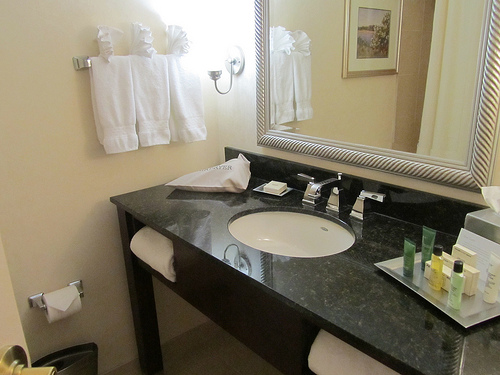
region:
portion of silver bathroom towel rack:
[70, 53, 97, 69]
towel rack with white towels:
[70, 18, 213, 148]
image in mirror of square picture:
[338, 1, 413, 86]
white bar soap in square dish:
[253, 174, 297, 204]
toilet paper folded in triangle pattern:
[45, 288, 86, 325]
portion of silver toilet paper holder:
[17, 289, 46, 311]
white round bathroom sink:
[229, 204, 364, 264]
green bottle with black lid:
[445, 260, 471, 308]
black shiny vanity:
[113, 148, 493, 373]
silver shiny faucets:
[296, 161, 383, 233]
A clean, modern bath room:
[13, 13, 486, 360]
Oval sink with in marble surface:
[221, 202, 363, 268]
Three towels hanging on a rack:
[83, 58, 210, 155]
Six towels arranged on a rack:
[68, 23, 204, 146]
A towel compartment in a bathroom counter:
[111, 203, 215, 305]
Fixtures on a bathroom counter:
[296, 166, 388, 229]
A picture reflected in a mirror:
[336, 3, 465, 190]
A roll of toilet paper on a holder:
[20, 277, 97, 326]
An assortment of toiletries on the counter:
[371, 222, 488, 334]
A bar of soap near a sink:
[253, 176, 320, 212]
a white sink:
[223, 203, 354, 260]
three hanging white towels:
[86, 50, 207, 150]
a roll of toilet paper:
[37, 282, 82, 322]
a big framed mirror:
[250, 0, 498, 195]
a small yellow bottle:
[427, 243, 442, 288]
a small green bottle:
[445, 257, 465, 308]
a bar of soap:
[262, 175, 285, 195]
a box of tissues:
[455, 175, 496, 242]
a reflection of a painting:
[338, 0, 403, 81]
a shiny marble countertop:
[105, 145, 499, 373]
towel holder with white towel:
[118, 221, 194, 283]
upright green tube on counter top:
[395, 229, 420, 284]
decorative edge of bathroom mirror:
[252, 129, 314, 158]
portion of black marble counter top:
[323, 283, 402, 325]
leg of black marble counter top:
[113, 189, 165, 365]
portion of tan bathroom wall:
[20, 120, 78, 240]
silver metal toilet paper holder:
[23, 289, 43, 322]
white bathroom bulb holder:
[207, 27, 245, 113]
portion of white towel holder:
[68, 54, 100, 90]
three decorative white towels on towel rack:
[90, 20, 214, 165]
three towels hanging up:
[83, 44, 213, 142]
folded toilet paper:
[33, 282, 95, 327]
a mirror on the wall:
[243, 4, 495, 191]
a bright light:
[198, 32, 253, 103]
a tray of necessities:
[396, 225, 498, 336]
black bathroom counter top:
[118, 144, 465, 338]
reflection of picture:
[316, 26, 455, 106]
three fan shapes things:
[71, 19, 197, 77]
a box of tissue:
[473, 172, 499, 252]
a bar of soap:
[249, 173, 296, 207]